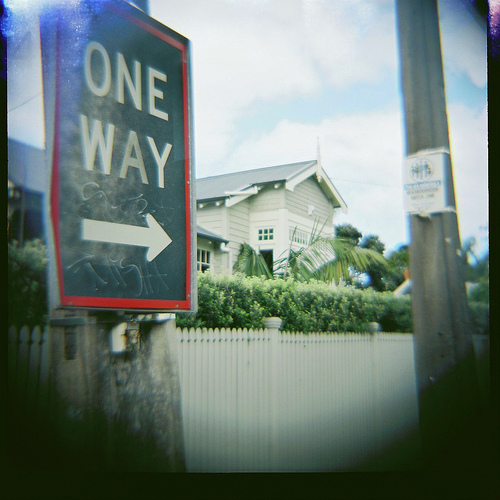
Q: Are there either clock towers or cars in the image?
A: No, there are no cars or clock towers.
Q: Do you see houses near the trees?
A: Yes, there is a house near the trees.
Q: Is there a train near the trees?
A: No, there is a house near the trees.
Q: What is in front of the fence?
A: The house is in front of the fence.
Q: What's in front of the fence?
A: The house is in front of the fence.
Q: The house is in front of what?
A: The house is in front of the fence.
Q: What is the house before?
A: The house is in front of the fence.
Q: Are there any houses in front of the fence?
A: Yes, there is a house in front of the fence.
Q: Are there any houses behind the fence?
A: No, the house is in front of the fence.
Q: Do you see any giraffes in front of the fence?
A: No, there is a house in front of the fence.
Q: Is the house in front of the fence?
A: Yes, the house is in front of the fence.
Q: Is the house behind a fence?
A: No, the house is in front of a fence.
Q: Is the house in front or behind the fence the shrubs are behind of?
A: The house is in front of the fence.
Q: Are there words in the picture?
A: Yes, there are words.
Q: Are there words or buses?
A: Yes, there are words.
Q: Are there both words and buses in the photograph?
A: No, there are words but no buses.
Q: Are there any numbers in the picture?
A: No, there are no numbers.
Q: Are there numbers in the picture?
A: No, there are no numbers.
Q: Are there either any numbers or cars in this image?
A: No, there are no numbers or cars.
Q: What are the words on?
A: The words are on the sign.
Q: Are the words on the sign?
A: Yes, the words are on the sign.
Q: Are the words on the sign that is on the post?
A: Yes, the words are on the sign.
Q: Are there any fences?
A: Yes, there is a fence.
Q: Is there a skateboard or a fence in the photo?
A: Yes, there is a fence.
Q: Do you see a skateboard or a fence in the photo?
A: Yes, there is a fence.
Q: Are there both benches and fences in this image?
A: No, there is a fence but no benches.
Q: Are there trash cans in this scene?
A: No, there are no trash cans.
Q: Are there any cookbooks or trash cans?
A: No, there are no trash cans or cookbooks.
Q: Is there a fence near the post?
A: Yes, there is a fence near the post.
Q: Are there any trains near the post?
A: No, there is a fence near the post.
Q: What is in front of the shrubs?
A: The fence is in front of the shrubs.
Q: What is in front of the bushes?
A: The fence is in front of the shrubs.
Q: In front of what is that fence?
A: The fence is in front of the shrubs.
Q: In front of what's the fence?
A: The fence is in front of the shrubs.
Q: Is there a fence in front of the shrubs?
A: Yes, there is a fence in front of the shrubs.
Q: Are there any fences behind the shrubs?
A: No, the fence is in front of the shrubs.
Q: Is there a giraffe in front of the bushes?
A: No, there is a fence in front of the bushes.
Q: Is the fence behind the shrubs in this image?
A: No, the fence is in front of the shrubs.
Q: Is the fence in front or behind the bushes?
A: The fence is in front of the bushes.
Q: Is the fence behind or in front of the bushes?
A: The fence is in front of the bushes.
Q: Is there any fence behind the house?
A: Yes, there is a fence behind the house.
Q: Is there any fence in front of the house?
A: No, the fence is behind the house.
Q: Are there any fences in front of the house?
A: No, the fence is behind the house.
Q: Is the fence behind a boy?
A: No, the fence is behind the house.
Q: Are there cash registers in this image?
A: No, there are no cash registers.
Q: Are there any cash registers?
A: No, there are no cash registers.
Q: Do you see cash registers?
A: No, there are no cash registers.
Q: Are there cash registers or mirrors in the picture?
A: No, there are no cash registers or mirrors.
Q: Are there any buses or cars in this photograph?
A: No, there are no cars or buses.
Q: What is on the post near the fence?
A: The sign is on the post.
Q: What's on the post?
A: The sign is on the post.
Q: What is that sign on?
A: The sign is on the post.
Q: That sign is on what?
A: The sign is on the post.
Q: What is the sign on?
A: The sign is on the post.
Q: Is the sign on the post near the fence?
A: Yes, the sign is on the post.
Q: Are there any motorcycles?
A: No, there are no motorcycles.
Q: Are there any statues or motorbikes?
A: No, there are no motorbikes or statues.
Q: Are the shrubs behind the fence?
A: Yes, the shrubs are behind the fence.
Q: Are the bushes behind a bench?
A: No, the bushes are behind the fence.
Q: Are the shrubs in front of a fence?
A: No, the shrubs are behind a fence.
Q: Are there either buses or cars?
A: No, there are no cars or buses.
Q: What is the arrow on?
A: The arrow is on the sign.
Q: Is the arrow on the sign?
A: Yes, the arrow is on the sign.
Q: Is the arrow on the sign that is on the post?
A: Yes, the arrow is on the sign.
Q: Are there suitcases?
A: No, there are no suitcases.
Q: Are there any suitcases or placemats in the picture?
A: No, there are no suitcases or placemats.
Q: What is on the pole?
A: The poster is on the pole.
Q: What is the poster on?
A: The poster is on the pole.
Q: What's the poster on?
A: The poster is on the pole.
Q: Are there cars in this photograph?
A: No, there are no cars.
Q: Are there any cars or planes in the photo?
A: No, there are no cars or planes.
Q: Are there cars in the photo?
A: No, there are no cars.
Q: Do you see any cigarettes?
A: No, there are no cigarettes.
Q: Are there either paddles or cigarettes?
A: No, there are no cigarettes or paddles.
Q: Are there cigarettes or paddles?
A: No, there are no cigarettes or paddles.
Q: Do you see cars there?
A: No, there are no cars.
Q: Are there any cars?
A: No, there are no cars.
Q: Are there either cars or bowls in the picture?
A: No, there are no cars or bowls.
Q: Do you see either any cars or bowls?
A: No, there are no cars or bowls.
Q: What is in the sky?
A: The clouds are in the sky.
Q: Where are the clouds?
A: The clouds are in the sky.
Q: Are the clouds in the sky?
A: Yes, the clouds are in the sky.